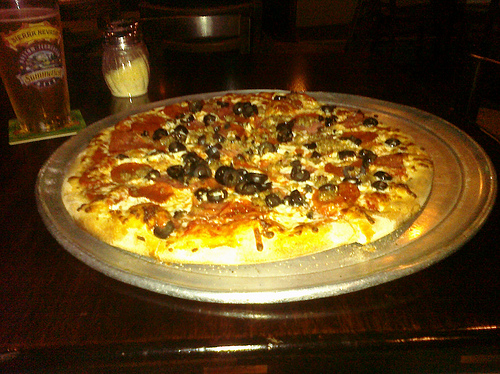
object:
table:
[0, 50, 499, 374]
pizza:
[60, 90, 436, 267]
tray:
[34, 88, 498, 305]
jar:
[100, 31, 154, 98]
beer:
[1, 7, 75, 134]